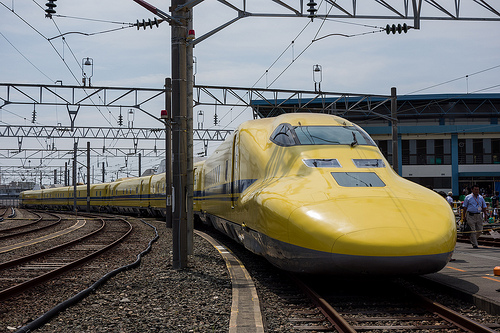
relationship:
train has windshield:
[18, 108, 458, 276] [289, 125, 373, 147]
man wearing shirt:
[460, 184, 491, 245] [461, 191, 489, 216]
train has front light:
[18, 108, 458, 276] [299, 151, 344, 173]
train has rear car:
[18, 108, 458, 276] [148, 162, 205, 220]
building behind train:
[254, 83, 498, 220] [18, 108, 458, 276]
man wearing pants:
[460, 184, 491, 245] [464, 211, 486, 246]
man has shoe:
[460, 184, 491, 245] [470, 238, 481, 250]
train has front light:
[18, 108, 458, 276] [354, 157, 387, 170]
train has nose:
[18, 108, 458, 276] [258, 166, 459, 266]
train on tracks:
[18, 108, 458, 276] [4, 207, 496, 332]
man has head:
[460, 184, 491, 245] [471, 182, 483, 199]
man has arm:
[460, 184, 491, 245] [458, 192, 470, 221]